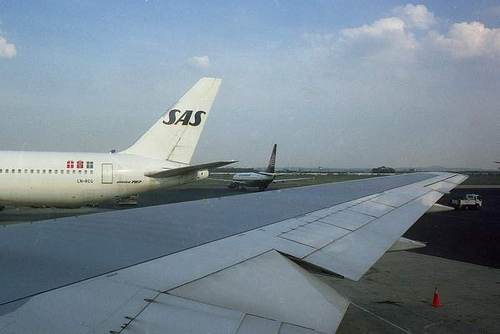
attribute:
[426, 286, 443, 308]
traffic cone — orange, white, small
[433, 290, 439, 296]
strip — white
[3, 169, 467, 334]
wing — gray, plane wing, metallic, long, metal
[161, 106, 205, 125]
writing — black lettered, word, sas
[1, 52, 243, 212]
plane — white, parked, big, jet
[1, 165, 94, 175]
windows — small, row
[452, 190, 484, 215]
truck — airport vehicle, white, driving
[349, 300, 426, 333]
line — painted, white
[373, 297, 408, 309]
spot — dark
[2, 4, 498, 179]
sky — blue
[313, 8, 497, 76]
clouds — puffy, white